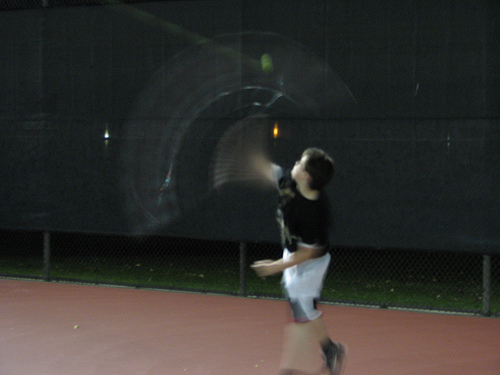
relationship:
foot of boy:
[323, 341, 343, 374] [208, 108, 350, 373]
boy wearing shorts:
[208, 108, 350, 373] [278, 252, 336, 318]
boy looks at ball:
[208, 113, 350, 374] [258, 51, 273, 68]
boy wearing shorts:
[208, 113, 350, 374] [250, 236, 345, 338]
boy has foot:
[208, 113, 350, 374] [321, 341, 348, 373]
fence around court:
[0, 226, 500, 318] [0, 88, 492, 282]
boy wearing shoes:
[208, 113, 350, 374] [315, 340, 362, 372]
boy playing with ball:
[208, 113, 350, 374] [156, 164, 180, 194]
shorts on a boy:
[282, 252, 332, 323] [208, 113, 350, 374]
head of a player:
[285, 145, 336, 188] [210, 120, 362, 365]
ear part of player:
[301, 170, 312, 182] [213, 106, 349, 374]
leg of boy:
[292, 283, 352, 373] [212, 117, 367, 373]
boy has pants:
[208, 113, 350, 374] [259, 225, 344, 319]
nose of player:
[288, 156, 301, 167] [228, 139, 352, 374]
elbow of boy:
[297, 241, 324, 257] [208, 113, 350, 374]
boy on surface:
[208, 113, 350, 374] [0, 275, 498, 373]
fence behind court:
[45, 203, 247, 303] [8, 260, 498, 372]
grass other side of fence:
[391, 228, 479, 301] [26, 184, 232, 312]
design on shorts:
[300, 290, 335, 320] [226, 230, 373, 346]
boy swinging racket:
[208, 113, 350, 374] [257, 98, 289, 214]